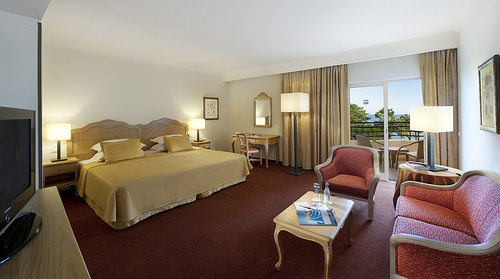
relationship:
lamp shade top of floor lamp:
[279, 91, 310, 114] [280, 90, 310, 177]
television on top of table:
[1, 105, 41, 263] [1, 183, 92, 278]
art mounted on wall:
[476, 52, 499, 136] [456, 8, 499, 180]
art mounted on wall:
[202, 94, 221, 121] [42, 37, 228, 166]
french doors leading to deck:
[346, 77, 426, 185] [350, 140, 426, 184]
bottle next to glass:
[322, 181, 332, 203] [309, 182, 321, 204]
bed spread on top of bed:
[76, 145, 253, 223] [65, 117, 252, 229]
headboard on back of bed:
[68, 115, 190, 162] [65, 117, 252, 229]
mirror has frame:
[254, 99, 270, 128] [253, 90, 274, 129]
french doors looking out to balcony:
[346, 77, 426, 185] [345, 121, 425, 183]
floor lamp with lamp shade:
[280, 90, 310, 177] [279, 91, 310, 114]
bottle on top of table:
[322, 181, 332, 203] [1, 183, 92, 278]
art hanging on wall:
[476, 52, 499, 136] [456, 8, 499, 180]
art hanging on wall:
[202, 94, 221, 121] [42, 37, 228, 166]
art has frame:
[476, 52, 499, 136] [476, 51, 499, 136]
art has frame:
[202, 94, 221, 121] [201, 95, 219, 121]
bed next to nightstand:
[65, 117, 252, 229] [43, 155, 79, 195]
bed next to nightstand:
[65, 117, 252, 229] [194, 136, 211, 150]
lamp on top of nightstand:
[44, 119, 72, 164] [43, 155, 79, 195]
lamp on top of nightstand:
[191, 117, 206, 143] [194, 136, 211, 150]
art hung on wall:
[202, 94, 221, 121] [42, 37, 228, 166]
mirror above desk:
[254, 99, 270, 128] [229, 130, 280, 169]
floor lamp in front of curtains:
[280, 90, 310, 177] [278, 63, 348, 171]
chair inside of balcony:
[391, 138, 426, 168] [345, 121, 425, 183]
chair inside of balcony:
[355, 131, 384, 167] [345, 121, 425, 183]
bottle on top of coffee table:
[322, 181, 332, 203] [272, 188, 355, 278]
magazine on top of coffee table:
[291, 200, 338, 229] [272, 188, 355, 278]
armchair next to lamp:
[314, 142, 380, 223] [408, 103, 455, 171]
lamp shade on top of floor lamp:
[279, 91, 310, 114] [280, 90, 310, 177]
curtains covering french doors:
[278, 63, 348, 171] [346, 77, 426, 185]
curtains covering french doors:
[416, 47, 458, 169] [346, 77, 426, 185]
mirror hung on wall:
[254, 99, 270, 128] [226, 72, 283, 164]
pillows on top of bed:
[90, 137, 147, 164] [65, 117, 252, 229]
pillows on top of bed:
[153, 131, 194, 155] [65, 117, 252, 229]